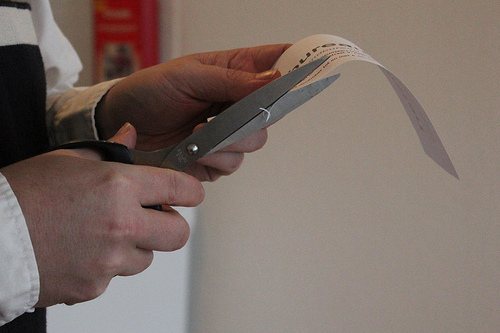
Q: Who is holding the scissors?
A: A person.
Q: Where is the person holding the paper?
A: One hand.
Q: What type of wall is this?
A: White.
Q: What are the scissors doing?
A: Cutting paper.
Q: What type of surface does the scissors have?
A: Sharp.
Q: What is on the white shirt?
A: Cuff.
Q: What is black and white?
A: The shirt.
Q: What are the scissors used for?
A: Cutting paper.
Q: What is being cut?
A: Paper.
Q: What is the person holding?
A: Scissors.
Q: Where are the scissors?
A: In hand.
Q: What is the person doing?
A: Cutting.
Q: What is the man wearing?
A: Long sleeved shirt.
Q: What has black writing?
A: The paper.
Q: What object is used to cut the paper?
A: Scissors.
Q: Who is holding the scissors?
A: A person.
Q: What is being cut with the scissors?
A: A piece of paper.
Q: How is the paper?
A: White with black writing.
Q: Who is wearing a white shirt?
A: A person.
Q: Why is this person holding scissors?
A: To cut the paper.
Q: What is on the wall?
A: A red object.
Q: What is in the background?
A: Beige wall.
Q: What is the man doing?
A: Cutting.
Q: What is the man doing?
A: Cutting.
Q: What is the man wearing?
A: Shirt.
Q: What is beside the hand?
A: Wall.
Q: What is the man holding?
A: Paper.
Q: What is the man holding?
A: Scissors.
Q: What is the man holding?
A: Nut.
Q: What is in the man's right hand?
A: Scissors.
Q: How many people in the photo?
A: One.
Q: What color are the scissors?
A: Black.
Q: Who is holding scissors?
A: A man.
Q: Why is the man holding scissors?
A: To cut paper.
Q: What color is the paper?
A: White.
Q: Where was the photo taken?
A: In a room.